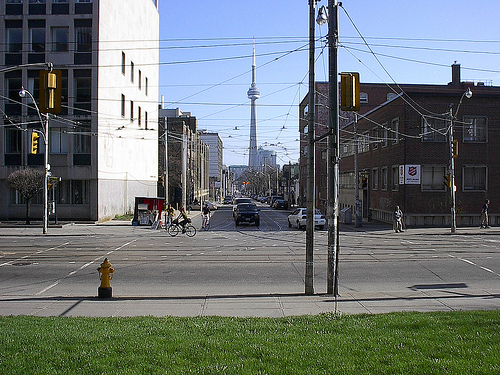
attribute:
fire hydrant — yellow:
[90, 253, 124, 304]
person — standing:
[388, 198, 414, 234]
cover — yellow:
[26, 130, 45, 158]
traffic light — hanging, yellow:
[25, 124, 51, 157]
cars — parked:
[241, 183, 295, 214]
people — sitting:
[239, 205, 260, 218]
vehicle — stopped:
[230, 200, 263, 229]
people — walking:
[162, 200, 219, 229]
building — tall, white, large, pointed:
[239, 37, 267, 168]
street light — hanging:
[334, 69, 365, 113]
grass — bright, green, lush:
[1, 314, 498, 374]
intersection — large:
[15, 57, 476, 310]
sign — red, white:
[393, 161, 424, 187]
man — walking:
[473, 196, 495, 229]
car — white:
[282, 202, 333, 231]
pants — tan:
[479, 211, 493, 231]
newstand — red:
[135, 194, 167, 226]